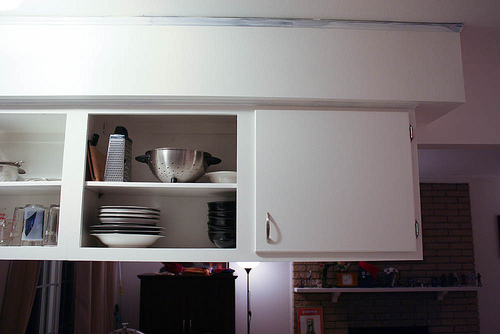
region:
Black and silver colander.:
[141, 138, 216, 192]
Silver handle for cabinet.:
[246, 197, 292, 267]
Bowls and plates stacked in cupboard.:
[89, 194, 157, 259]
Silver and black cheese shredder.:
[89, 118, 138, 204]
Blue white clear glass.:
[0, 196, 56, 256]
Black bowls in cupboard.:
[185, 199, 232, 269]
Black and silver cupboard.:
[137, 264, 228, 331]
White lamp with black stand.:
[232, 265, 258, 331]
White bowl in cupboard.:
[202, 160, 249, 184]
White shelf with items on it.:
[304, 263, 496, 306]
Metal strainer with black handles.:
[133, 146, 222, 184]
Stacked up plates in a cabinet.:
[86, 201, 168, 246]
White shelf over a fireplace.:
[291, 283, 481, 298]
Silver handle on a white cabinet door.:
[264, 210, 272, 242]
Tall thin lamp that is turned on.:
[236, 258, 258, 332]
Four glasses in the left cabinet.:
[5, 203, 59, 246]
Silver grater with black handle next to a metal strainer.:
[100, 124, 132, 183]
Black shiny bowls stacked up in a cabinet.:
[205, 198, 239, 248]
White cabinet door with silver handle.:
[251, 106, 418, 253]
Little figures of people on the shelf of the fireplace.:
[428, 271, 483, 288]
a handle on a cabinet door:
[262, 213, 275, 244]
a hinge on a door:
[411, 220, 423, 242]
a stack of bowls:
[204, 202, 234, 256]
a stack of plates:
[87, 203, 172, 245]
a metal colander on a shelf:
[128, 141, 216, 189]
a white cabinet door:
[238, 100, 328, 257]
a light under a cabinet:
[235, 257, 269, 276]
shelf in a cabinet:
[88, 172, 240, 194]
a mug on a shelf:
[6, 199, 50, 249]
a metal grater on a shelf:
[101, 125, 134, 186]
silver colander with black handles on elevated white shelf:
[134, 145, 221, 182]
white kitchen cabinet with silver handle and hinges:
[251, 111, 421, 257]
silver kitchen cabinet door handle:
[260, 212, 279, 244]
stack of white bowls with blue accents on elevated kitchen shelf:
[87, 201, 165, 245]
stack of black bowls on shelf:
[204, 200, 239, 247]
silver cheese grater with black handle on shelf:
[101, 123, 133, 180]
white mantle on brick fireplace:
[291, 279, 483, 303]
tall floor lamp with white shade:
[233, 261, 268, 333]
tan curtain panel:
[71, 260, 121, 332]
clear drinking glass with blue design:
[10, 202, 50, 249]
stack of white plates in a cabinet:
[82, 183, 172, 248]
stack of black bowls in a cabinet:
[202, 190, 240, 247]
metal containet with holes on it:
[136, 137, 221, 183]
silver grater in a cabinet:
[103, 119, 133, 184]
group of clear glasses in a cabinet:
[0, 190, 61, 248]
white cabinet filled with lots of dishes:
[0, 110, 238, 259]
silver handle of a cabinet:
[259, 209, 278, 247]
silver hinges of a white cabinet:
[409, 124, 415, 139]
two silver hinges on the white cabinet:
[405, 118, 420, 245]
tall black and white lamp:
[239, 260, 259, 332]